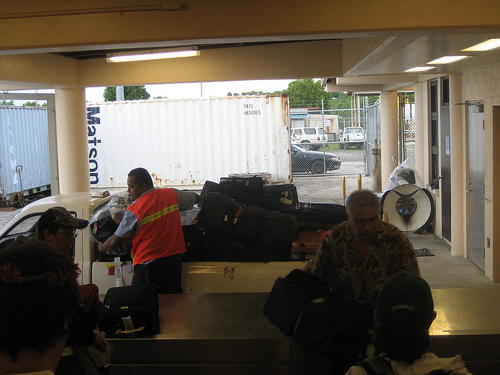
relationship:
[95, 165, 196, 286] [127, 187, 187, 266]
man wearing vest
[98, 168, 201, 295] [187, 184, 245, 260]
man loading bag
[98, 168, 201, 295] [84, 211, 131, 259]
man loading bag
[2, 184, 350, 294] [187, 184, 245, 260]
truck has bag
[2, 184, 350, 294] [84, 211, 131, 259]
truck has bag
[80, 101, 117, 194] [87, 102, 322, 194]
lettering on container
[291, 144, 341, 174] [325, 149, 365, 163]
car parked on street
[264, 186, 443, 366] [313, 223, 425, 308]
man wearing shirt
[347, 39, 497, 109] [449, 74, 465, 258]
building has pillar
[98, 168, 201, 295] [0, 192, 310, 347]
man standing next to truck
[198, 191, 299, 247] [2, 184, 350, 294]
luggage in back of truck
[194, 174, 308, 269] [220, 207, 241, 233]
luggage has strap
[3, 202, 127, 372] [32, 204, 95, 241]
person wearing hat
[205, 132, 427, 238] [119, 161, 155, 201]
person has head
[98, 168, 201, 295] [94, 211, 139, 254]
man has arm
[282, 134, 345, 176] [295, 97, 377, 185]
car behind fence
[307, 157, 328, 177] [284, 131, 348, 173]
tire on car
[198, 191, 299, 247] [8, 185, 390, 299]
luggage in truck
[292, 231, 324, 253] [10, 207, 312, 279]
luggage in truck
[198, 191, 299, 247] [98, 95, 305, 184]
luggage in truck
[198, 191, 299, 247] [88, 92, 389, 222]
luggage in truck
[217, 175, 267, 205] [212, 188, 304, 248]
luggage in truck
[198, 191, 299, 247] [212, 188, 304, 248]
luggage in truck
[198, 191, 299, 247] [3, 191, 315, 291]
luggage in truck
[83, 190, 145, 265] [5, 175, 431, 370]
luggage in truck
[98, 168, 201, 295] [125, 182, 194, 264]
man in vest